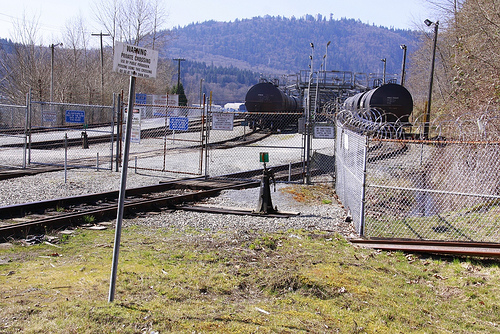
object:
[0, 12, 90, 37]
wire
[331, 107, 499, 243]
fence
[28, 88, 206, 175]
gate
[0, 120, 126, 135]
tracks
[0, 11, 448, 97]
mounts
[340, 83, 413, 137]
cars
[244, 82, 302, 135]
cars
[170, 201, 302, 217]
plank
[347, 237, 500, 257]
plank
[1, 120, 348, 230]
ground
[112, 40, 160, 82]
sign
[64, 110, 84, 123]
sign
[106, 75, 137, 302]
pole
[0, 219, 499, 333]
grass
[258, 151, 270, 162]
flag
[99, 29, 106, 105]
poles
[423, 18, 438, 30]
lamp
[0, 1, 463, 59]
sky